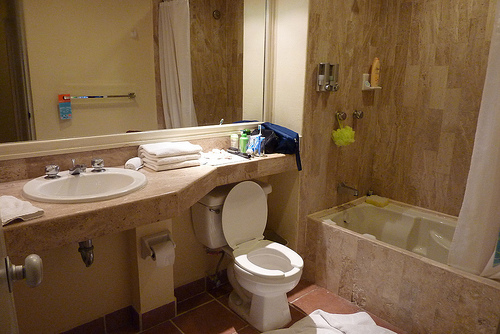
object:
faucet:
[43, 157, 105, 179]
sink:
[19, 166, 146, 205]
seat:
[231, 240, 305, 277]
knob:
[2, 253, 42, 287]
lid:
[221, 180, 268, 250]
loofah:
[331, 109, 356, 147]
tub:
[305, 195, 500, 333]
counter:
[2, 131, 295, 327]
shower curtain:
[157, 3, 192, 130]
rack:
[57, 92, 136, 103]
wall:
[1, 0, 245, 140]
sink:
[77, 239, 96, 268]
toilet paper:
[140, 230, 177, 267]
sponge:
[331, 126, 356, 147]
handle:
[336, 111, 347, 121]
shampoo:
[370, 57, 381, 87]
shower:
[314, 43, 500, 296]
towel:
[264, 309, 400, 333]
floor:
[61, 273, 416, 334]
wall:
[390, 0, 493, 123]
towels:
[123, 141, 203, 172]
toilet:
[220, 181, 305, 332]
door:
[4, 211, 47, 331]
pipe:
[78, 240, 95, 268]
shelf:
[362, 72, 382, 91]